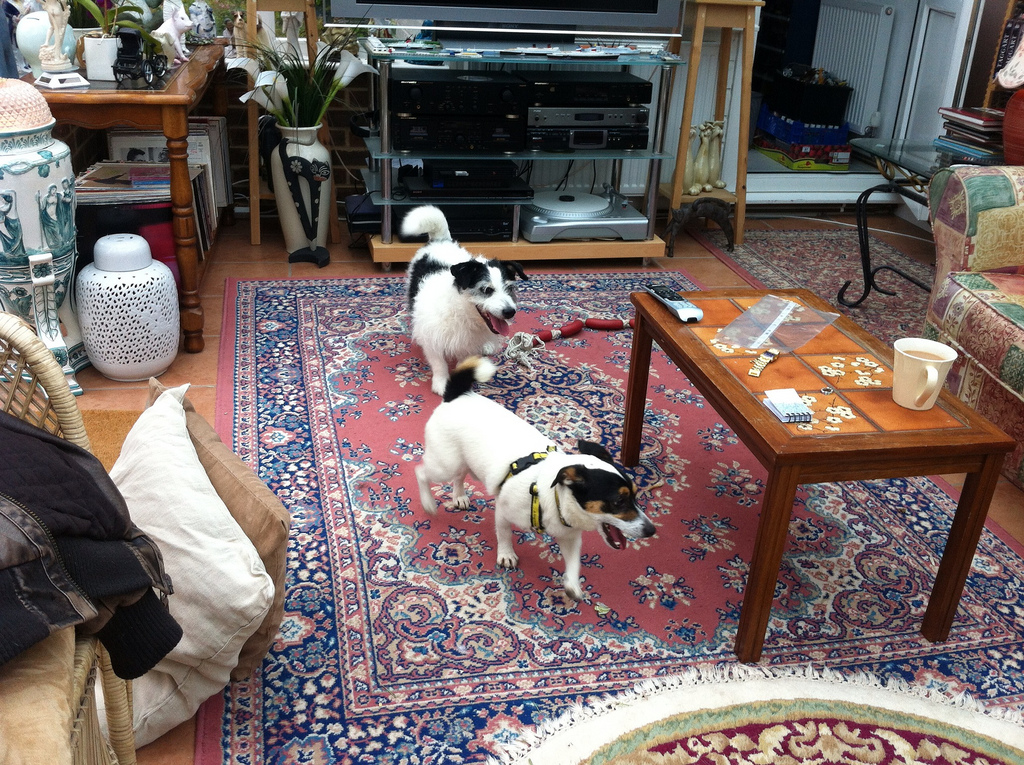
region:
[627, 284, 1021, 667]
a wooden coffee table on a carpet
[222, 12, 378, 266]
Calla lilies in a white jar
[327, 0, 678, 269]
an entertainment unit below a wide silver TV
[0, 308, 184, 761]
a black jacket sitting on a chair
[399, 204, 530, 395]
a white and black dog waging its tail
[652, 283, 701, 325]
a silver remote with black buttons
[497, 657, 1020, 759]
a round carpet with white fringe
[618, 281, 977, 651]
a wooden coffee table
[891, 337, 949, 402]
a white mug on a table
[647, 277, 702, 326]
a remote on the table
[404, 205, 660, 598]
two dogs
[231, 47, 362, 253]
a vase with flowers in it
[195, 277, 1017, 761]
a rug on the floor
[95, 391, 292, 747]
pillows on the floor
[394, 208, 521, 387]
a black and white dog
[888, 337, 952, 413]
a white coffee mug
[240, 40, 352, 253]
a white vase with flowers in it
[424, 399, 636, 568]
a dog in a yellow harness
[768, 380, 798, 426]
a notebook on the coffee table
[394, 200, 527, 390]
fluffy white and black dog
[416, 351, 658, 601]
dog wearing black and yellow harness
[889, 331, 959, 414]
white coffee mug with coffee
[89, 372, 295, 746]
two pillows lying on the floor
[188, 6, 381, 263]
fake flowers in tall white vase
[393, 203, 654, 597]
two dogs playing in a living room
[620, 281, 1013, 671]
brown wood coffee table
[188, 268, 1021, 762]
large decorative oriental rug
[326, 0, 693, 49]
large silver flatscreen television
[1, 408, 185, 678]
brown leather jacket on a chair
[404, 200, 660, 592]
Black and white dogs on a rug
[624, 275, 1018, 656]
Wood table on a rug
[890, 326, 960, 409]
Cup sitting on a table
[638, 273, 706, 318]
Remote control laying on a table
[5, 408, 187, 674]
A coat laying on a chair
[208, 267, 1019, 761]
A rug on the floor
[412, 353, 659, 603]
a small dog next to a table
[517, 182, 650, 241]
a record player at bottom of entertainment center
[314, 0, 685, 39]
a television on top of an entertainment center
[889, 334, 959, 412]
a mug on top of a table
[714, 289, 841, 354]
a plastic bag on top of a table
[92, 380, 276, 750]
a white pillow next to a chair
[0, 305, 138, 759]
a chair next to a white pillow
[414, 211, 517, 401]
a dog walking inside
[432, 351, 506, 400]
a tail on the dog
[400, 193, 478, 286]
a tail on the dog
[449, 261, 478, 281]
an ear on the dog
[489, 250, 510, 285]
an ear on the dog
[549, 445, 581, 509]
an ear on the dog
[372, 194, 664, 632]
Two dogs on top of an area rug.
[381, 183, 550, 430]
A black and white dog.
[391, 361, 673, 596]
A black, white, and brown dog.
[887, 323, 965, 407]
A white coffee mug.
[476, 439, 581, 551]
A yellow and black harness on a dog.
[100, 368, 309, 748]
A brown and beige pillow on the ground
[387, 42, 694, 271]
An entertainment stand.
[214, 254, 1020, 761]
A large area rug designed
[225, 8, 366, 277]
Flowers in a tall white vase.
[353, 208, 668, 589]
Dogs on a rug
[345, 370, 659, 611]
Dog on the rug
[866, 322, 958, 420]
Mug on the table